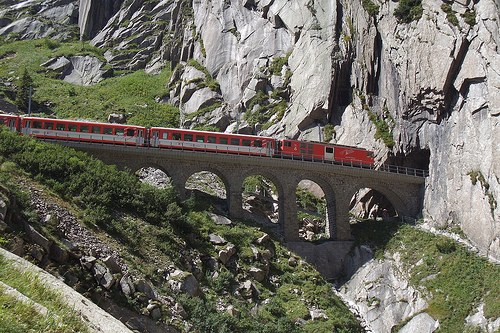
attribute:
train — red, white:
[0, 113, 374, 169]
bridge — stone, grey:
[36, 140, 429, 259]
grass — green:
[1, 0, 499, 331]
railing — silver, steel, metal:
[10, 127, 429, 179]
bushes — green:
[8, 141, 292, 332]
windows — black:
[1, 118, 334, 154]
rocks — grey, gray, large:
[2, 2, 499, 332]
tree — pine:
[21, 68, 36, 100]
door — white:
[323, 146, 335, 161]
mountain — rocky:
[12, 2, 499, 261]